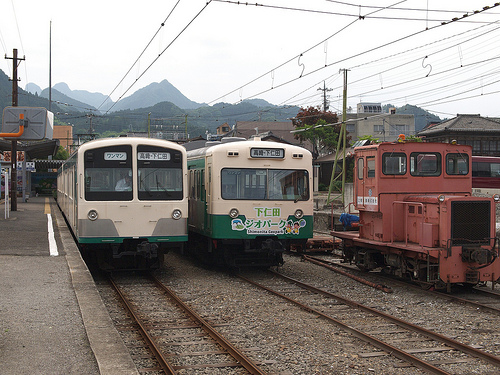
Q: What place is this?
A: It is a train station.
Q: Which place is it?
A: It is a train station.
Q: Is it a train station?
A: Yes, it is a train station.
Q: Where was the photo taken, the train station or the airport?
A: It was taken at the train station.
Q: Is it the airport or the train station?
A: It is the train station.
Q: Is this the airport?
A: No, it is the train station.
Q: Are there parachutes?
A: No, there are no parachutes.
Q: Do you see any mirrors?
A: No, there are no mirrors.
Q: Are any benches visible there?
A: No, there are no benches.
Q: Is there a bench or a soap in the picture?
A: No, there are no benches or soaps.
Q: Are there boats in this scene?
A: No, there are no boats.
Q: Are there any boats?
A: No, there are no boats.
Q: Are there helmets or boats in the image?
A: No, there are no boats or helmets.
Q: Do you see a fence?
A: No, there are no fences.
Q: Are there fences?
A: No, there are no fences.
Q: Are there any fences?
A: No, there are no fences.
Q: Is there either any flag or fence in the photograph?
A: No, there are no fences or flags.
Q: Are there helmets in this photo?
A: No, there are no helmets.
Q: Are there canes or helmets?
A: No, there are no helmets or canes.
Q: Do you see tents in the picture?
A: No, there are no tents.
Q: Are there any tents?
A: No, there are no tents.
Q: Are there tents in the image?
A: No, there are no tents.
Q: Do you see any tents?
A: No, there are no tents.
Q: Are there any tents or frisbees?
A: No, there are no tents or frisbees.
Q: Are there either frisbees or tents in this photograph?
A: No, there are no tents or frisbees.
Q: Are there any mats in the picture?
A: No, there are no mats.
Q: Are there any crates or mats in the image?
A: No, there are no mats or crates.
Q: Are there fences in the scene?
A: No, there are no fences.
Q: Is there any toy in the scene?
A: No, there are no toys.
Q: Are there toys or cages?
A: No, there are no toys or cages.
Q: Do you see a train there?
A: Yes, there are trains.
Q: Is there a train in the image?
A: Yes, there are trains.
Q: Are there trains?
A: Yes, there are trains.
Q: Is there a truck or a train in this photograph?
A: Yes, there are trains.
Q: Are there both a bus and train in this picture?
A: No, there are trains but no buses.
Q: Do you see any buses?
A: No, there are no buses.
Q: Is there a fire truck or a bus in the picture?
A: No, there are no buses or fire trucks.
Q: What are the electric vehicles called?
A: The vehicles are trains.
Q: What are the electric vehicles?
A: The vehicles are trains.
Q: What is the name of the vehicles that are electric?
A: The vehicles are trains.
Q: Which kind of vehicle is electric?
A: The vehicle is trains.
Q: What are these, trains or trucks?
A: These are trains.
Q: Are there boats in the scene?
A: No, there are no boats.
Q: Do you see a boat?
A: No, there are no boats.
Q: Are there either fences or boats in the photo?
A: No, there are no boats or fences.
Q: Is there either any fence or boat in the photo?
A: No, there are no boats or fences.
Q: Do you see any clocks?
A: No, there are no clocks.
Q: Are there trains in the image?
A: Yes, there is a train.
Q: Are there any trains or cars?
A: Yes, there is a train.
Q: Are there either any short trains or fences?
A: Yes, there is a short train.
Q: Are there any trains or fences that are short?
A: Yes, the train is short.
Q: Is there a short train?
A: Yes, there is a short train.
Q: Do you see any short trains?
A: Yes, there is a short train.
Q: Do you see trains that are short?
A: Yes, there is a train that is short.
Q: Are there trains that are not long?
A: Yes, there is a short train.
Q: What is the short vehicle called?
A: The vehicle is a train.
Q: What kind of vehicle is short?
A: The vehicle is a train.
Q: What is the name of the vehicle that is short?
A: The vehicle is a train.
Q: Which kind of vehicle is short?
A: The vehicle is a train.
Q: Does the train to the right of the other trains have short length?
A: Yes, the train is short.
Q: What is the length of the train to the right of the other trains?
A: The train is short.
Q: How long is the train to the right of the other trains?
A: The train is short.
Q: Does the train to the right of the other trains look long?
A: No, the train is short.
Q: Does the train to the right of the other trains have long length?
A: No, the train is short.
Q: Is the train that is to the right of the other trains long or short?
A: The train is short.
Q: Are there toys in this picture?
A: No, there are no toys.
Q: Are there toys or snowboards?
A: No, there are no toys or snowboards.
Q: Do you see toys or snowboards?
A: No, there are no toys or snowboards.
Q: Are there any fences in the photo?
A: No, there are no fences.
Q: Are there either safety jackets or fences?
A: No, there are no fences or safety jackets.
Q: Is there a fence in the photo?
A: No, there are no fences.